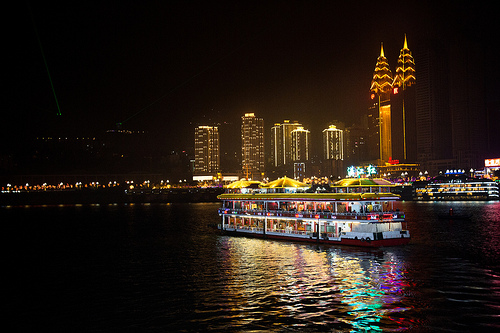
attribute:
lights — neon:
[220, 170, 393, 195]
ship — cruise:
[217, 174, 407, 246]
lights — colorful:
[287, 241, 419, 331]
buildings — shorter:
[183, 33, 439, 182]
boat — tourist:
[195, 51, 450, 256]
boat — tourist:
[214, 184, 411, 252]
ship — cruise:
[215, 191, 410, 244]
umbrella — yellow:
[222, 176, 267, 193]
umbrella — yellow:
[264, 176, 311, 191]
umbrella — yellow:
[333, 173, 397, 191]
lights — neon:
[210, 167, 402, 325]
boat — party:
[213, 176, 410, 246]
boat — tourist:
[242, 181, 469, 241]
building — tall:
[361, 28, 428, 185]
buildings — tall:
[144, 49, 423, 189]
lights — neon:
[237, 188, 406, 235]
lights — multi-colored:
[232, 210, 396, 220]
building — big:
[189, 116, 226, 185]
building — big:
[240, 110, 264, 180]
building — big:
[273, 119, 311, 178]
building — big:
[319, 124, 348, 174]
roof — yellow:
[217, 186, 397, 203]